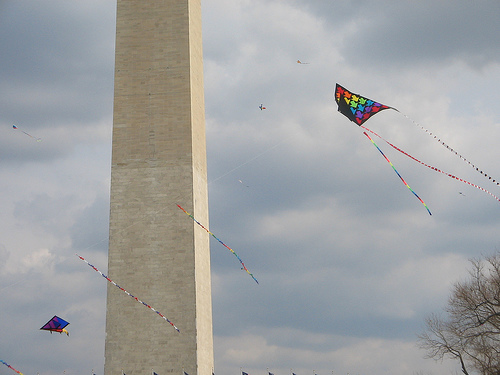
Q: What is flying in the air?
A: Kites.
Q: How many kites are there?
A: Five.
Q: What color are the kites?
A: Multi-colored.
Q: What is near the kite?
A: Pole.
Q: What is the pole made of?
A: Cement.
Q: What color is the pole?
A: Tan.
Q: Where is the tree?
A: Background.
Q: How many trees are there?
A: One.